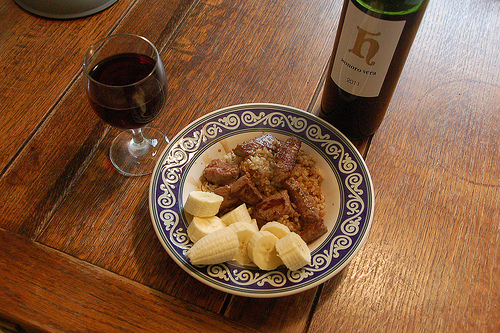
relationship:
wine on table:
[320, 0, 430, 138] [0, 0, 500, 332]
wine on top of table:
[320, 0, 430, 138] [0, 0, 500, 332]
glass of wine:
[81, 30, 176, 178] [320, 0, 430, 138]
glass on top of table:
[81, 30, 176, 178] [0, 0, 500, 332]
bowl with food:
[149, 103, 377, 300] [185, 132, 327, 271]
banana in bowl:
[182, 188, 315, 273] [149, 103, 377, 300]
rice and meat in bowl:
[200, 131, 331, 240] [149, 103, 377, 300]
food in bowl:
[185, 132, 327, 271] [149, 103, 377, 300]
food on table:
[185, 132, 327, 271] [0, 0, 500, 332]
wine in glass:
[89, 50, 167, 127] [81, 30, 176, 178]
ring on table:
[415, 73, 499, 190] [0, 0, 500, 332]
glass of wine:
[81, 30, 176, 178] [89, 50, 167, 127]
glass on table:
[81, 30, 176, 178] [0, 0, 500, 332]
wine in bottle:
[320, 0, 430, 138] [322, 0, 431, 129]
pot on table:
[8, 0, 125, 21] [0, 0, 500, 332]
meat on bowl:
[272, 132, 302, 181] [149, 103, 377, 300]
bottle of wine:
[322, 0, 431, 129] [320, 0, 430, 138]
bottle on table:
[322, 0, 431, 129] [0, 0, 500, 332]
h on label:
[348, 24, 382, 66] [330, 0, 406, 98]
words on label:
[339, 56, 381, 77] [330, 0, 406, 98]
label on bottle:
[330, 0, 406, 98] [322, 0, 431, 129]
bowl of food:
[149, 103, 377, 300] [185, 132, 327, 271]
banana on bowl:
[182, 188, 315, 273] [149, 103, 377, 300]